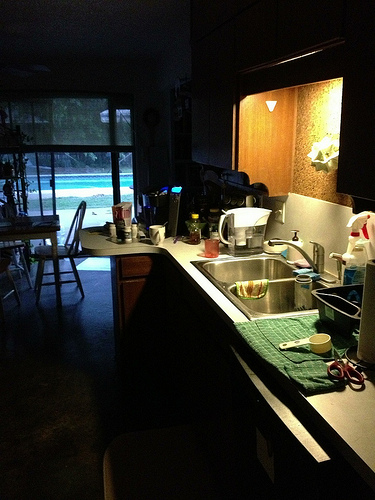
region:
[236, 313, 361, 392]
Dish towel on counter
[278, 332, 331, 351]
Measuring cup on dish towel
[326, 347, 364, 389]
Scissors with a colorful handle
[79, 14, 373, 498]
A scene in the kitchen area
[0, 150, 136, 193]
A pool outside of the house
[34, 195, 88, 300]
A wooden chair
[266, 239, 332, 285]
A silver faucet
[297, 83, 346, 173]
A light on the wall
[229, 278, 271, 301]
A rag hanging on the sink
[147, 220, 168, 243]
A cup on the kitchen counter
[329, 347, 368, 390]
Red handled scissors lying on dish towel.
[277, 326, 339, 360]
Measuring cup lying on green dish towel.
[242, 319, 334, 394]
Green dish towel lying on kitchen counter.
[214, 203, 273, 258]
Water filter container sitting on kitchen counter.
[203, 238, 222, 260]
Pink cup sitting on kitchen counter.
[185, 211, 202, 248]
Bottle of honey sitting on kitchen counter.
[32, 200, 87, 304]
Chair sitting at kitchen table.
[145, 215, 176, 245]
Coffee cup with spoon sitting on kitchen counter.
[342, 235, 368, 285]
Blue dish detergent sitting by kitchen sink.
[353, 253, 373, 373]
Edge of roll of towel paper sitting on kitchen counter.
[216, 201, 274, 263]
water pitcher sitting on cabient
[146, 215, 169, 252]
white coffee cup with spoon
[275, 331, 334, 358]
white measuring cup on counter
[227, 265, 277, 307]
brown and white stripped dishcloth with green trim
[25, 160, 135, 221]
view of pool on back sliding door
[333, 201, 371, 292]
spray bottle with red detail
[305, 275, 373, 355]
black dish drainer sitting on kitchen cabient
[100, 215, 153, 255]
three pill bottles sitting on edge on kitchen cabinet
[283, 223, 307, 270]
white soap dispenser with brown top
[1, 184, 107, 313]
wooden chair at end on kitchen table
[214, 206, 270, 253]
a white and clear pitcher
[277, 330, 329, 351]
a white measuring cup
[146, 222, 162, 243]
a white mug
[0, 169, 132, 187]
an in-ground swimming pool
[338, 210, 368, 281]
a red and white spray bottle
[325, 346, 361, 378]
pair of red scissors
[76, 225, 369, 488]
white cluttered kitchen counter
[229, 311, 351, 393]
green dish towel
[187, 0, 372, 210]
brown kitchen cabinet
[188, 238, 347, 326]
stainless steel kitchen sink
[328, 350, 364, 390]
Scissors with red handle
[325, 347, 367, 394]
Scissors on white counter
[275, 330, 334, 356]
White plastic measuring cup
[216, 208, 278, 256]
Water filtration system pitcher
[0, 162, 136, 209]
in ground pool in backyard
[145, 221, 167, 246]
White coffee cup on counter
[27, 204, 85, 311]
wooden chair at table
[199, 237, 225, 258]
red glass on counter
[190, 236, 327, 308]
stainless steel sink with double basin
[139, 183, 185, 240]
coffee maker with blue light